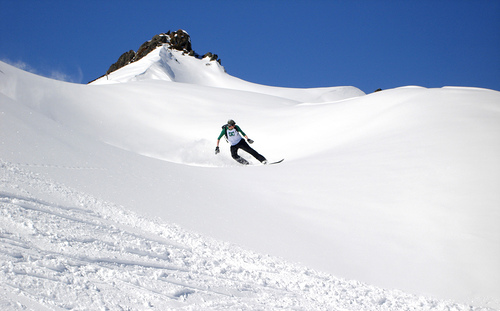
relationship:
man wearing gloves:
[215, 119, 268, 165] [210, 143, 221, 155]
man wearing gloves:
[215, 119, 268, 165] [247, 136, 254, 144]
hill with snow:
[85, 26, 249, 84] [1, 43, 498, 309]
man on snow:
[216, 120, 267, 165] [1, 43, 498, 309]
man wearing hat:
[215, 119, 268, 165] [226, 116, 236, 126]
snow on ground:
[1, 43, 498, 309] [7, 56, 497, 308]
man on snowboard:
[215, 119, 268, 165] [263, 151, 286, 166]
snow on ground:
[0, 192, 497, 309] [2, 28, 496, 305]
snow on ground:
[0, 192, 497, 309] [7, 56, 497, 308]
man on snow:
[215, 119, 268, 165] [102, 74, 392, 239]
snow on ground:
[1, 43, 498, 309] [0, 162, 497, 307]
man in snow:
[215, 119, 268, 165] [1, 43, 498, 309]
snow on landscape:
[1, 43, 498, 309] [40, 73, 265, 199]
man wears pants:
[215, 119, 268, 165] [226, 140, 266, 165]